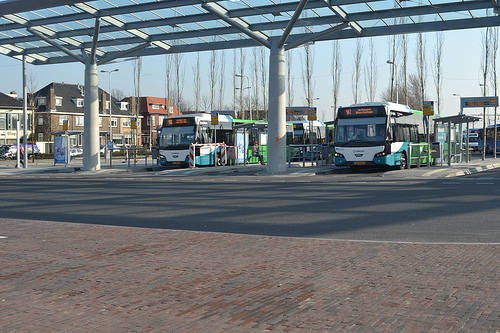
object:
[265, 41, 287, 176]
pylon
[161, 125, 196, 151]
front window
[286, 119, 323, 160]
bus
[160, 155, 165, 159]
headlight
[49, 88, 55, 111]
chimney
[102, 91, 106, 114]
chimney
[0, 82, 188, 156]
building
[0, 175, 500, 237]
shade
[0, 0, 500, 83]
sky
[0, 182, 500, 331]
tarmac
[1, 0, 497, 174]
frame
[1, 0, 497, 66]
roof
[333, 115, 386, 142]
window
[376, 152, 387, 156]
headlight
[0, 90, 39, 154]
house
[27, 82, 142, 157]
house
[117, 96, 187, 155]
house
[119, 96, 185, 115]
red roof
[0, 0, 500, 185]
structure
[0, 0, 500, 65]
metal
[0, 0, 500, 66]
framework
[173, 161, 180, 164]
plate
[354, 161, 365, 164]
plate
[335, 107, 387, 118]
display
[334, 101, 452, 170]
bus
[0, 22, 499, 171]
bus station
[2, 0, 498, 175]
shelter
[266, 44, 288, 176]
pillar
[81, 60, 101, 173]
pillar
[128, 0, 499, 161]
trees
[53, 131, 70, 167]
placard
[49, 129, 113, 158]
shelter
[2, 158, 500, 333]
floor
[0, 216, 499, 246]
line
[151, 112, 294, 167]
bus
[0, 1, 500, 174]
terminal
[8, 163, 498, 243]
ground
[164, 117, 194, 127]
display